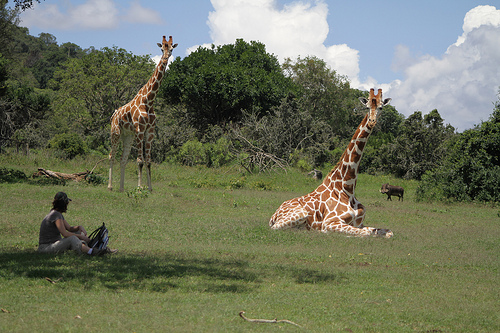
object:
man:
[36, 192, 106, 258]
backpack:
[90, 222, 110, 258]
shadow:
[0, 255, 335, 295]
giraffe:
[269, 87, 396, 241]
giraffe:
[108, 36, 177, 194]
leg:
[145, 125, 155, 191]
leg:
[136, 129, 143, 189]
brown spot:
[326, 198, 337, 210]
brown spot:
[152, 82, 158, 91]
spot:
[358, 130, 370, 139]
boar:
[380, 184, 404, 202]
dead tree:
[30, 159, 108, 185]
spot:
[336, 204, 347, 216]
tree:
[165, 38, 285, 122]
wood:
[27, 168, 101, 186]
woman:
[37, 191, 117, 258]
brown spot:
[356, 140, 365, 151]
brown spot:
[334, 181, 342, 191]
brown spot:
[139, 116, 146, 124]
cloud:
[201, 0, 359, 70]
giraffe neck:
[321, 124, 376, 192]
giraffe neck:
[131, 59, 170, 107]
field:
[4, 158, 499, 331]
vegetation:
[0, 0, 500, 291]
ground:
[8, 155, 497, 325]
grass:
[4, 152, 496, 332]